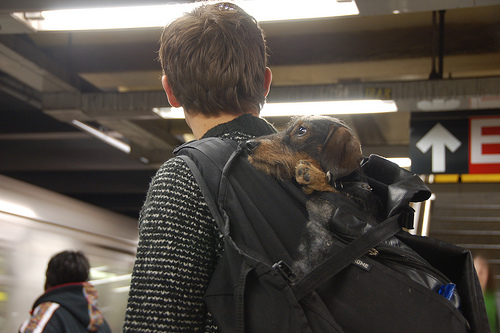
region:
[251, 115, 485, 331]
Dog in black back pack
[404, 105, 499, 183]
Sign with white arrow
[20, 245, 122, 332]
Person wearing hooded jacket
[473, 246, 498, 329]
Woman wearing green shirt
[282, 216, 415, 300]
Black strap on back pack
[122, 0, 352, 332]
Man wearing gray sweater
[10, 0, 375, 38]
overhead light on ceiling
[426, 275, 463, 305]
Blue tag on bookbag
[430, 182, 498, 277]
Brown stairs in background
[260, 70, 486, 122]
Metal beam hanging overhead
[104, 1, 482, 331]
Man carrying a dog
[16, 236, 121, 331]
Man wearing hooded coat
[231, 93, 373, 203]
Dog looks sad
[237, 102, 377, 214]
Dog on back of man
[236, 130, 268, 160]
Nose of dog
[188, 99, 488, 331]
Dog is keep in a backpack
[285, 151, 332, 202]
Paw of dog stick out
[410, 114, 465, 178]
White arrow pointing up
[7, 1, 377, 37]
Florescent light in ceiling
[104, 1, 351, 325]
Man wears black and white sweater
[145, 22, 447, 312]
man carrying dog on his back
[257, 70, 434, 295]
dog in dog carrier on mans back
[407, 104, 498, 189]
white arrow on black sign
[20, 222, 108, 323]
person wearing black, red, white jacket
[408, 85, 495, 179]
sign with yellow stripe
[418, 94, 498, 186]
sign with large white E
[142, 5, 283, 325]
man in black and white shirt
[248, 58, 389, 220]
brown dog on mans back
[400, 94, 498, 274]
exit sign over stair case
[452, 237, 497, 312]
person wearing green shirt in background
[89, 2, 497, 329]
a boy at an airport carrying a dog in a backpack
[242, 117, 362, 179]
a dog sticking his head out of a backpack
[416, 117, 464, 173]
a white up arrow on a sign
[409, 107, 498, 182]
a sign at an airport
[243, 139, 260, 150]
a dog's nose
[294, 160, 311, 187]
a dog's paw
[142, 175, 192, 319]
the sleeve of a boy's sweater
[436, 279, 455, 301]
a pen sticking out of a backpack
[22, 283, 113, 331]
a person's jacket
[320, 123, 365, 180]
a dog's floppy ear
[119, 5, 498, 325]
a kid with a backpack on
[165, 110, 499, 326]
a black backpack with a dog inside it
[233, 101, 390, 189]
a dog popping its head out of a backpack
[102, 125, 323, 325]
a white and back sweater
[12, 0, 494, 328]
a scene in a subway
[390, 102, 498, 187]
a sign attached to a ceiling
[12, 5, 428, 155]
a row of lights on a ceiling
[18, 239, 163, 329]
a person waiting for a train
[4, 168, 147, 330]
a moving white train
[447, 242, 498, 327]
a person in the distance wearing green